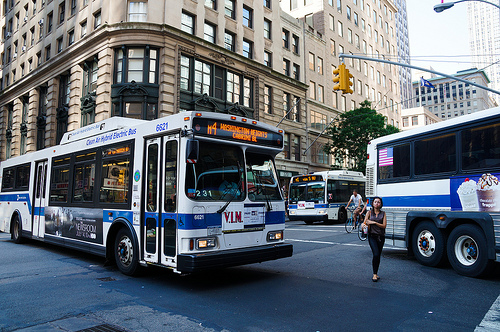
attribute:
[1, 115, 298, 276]
bus — white, transit, large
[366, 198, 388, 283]
woman — crossing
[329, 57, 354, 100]
stoplight — overhead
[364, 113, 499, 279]
bus — white, transit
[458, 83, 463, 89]
window — black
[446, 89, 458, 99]
window — black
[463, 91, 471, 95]
window — black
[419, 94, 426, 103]
window — black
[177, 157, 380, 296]
intersection — busy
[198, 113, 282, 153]
sign — digital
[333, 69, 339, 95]
light — suspended, yellow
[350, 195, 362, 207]
shirt — grey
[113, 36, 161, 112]
window — large